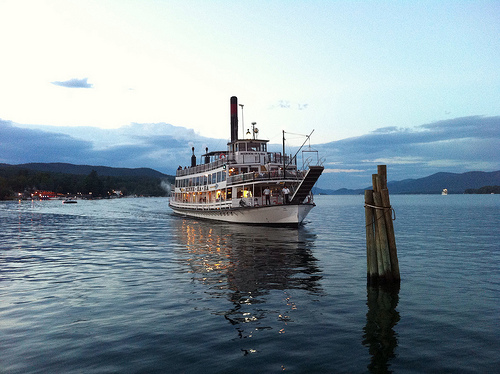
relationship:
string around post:
[363, 199, 388, 212] [337, 176, 410, 278]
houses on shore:
[24, 185, 59, 205] [116, 202, 151, 216]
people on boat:
[229, 178, 295, 206] [131, 124, 323, 227]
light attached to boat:
[287, 208, 300, 220] [131, 124, 323, 227]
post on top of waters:
[337, 176, 410, 278] [14, 206, 90, 302]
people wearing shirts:
[229, 178, 295, 206] [241, 188, 292, 200]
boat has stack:
[131, 124, 323, 227] [226, 96, 244, 142]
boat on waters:
[131, 124, 323, 227] [14, 206, 90, 302]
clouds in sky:
[59, 78, 94, 88] [246, 9, 380, 94]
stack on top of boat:
[226, 96, 244, 142] [131, 124, 323, 227]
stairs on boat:
[299, 181, 305, 203] [131, 124, 323, 227]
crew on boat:
[241, 161, 295, 182] [131, 124, 323, 227]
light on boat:
[287, 208, 300, 220] [131, 124, 323, 227]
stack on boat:
[226, 96, 244, 142] [131, 124, 323, 227]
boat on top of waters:
[131, 124, 323, 227] [14, 206, 90, 302]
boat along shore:
[131, 124, 323, 227] [116, 202, 151, 216]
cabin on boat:
[236, 138, 290, 175] [131, 124, 323, 227]